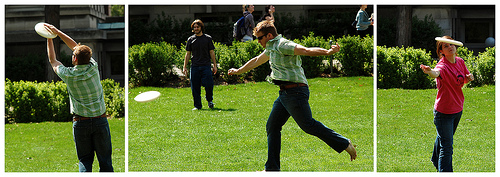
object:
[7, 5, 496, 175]
collage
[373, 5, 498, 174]
pictures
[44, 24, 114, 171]
man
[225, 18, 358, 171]
man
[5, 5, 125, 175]
left picture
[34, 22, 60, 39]
frisbee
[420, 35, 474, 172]
woman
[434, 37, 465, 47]
frisbee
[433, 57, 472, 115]
shirt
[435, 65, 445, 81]
short sleeves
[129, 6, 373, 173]
middle picture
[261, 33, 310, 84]
shirt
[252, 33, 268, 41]
sunglasses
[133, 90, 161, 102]
frisbee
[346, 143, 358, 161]
foot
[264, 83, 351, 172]
jeans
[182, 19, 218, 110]
man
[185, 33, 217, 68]
shirt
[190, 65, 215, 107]
jeans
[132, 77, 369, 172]
grass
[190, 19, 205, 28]
hair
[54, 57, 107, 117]
shirt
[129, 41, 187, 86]
bushes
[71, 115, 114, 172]
jeans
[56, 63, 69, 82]
short sleeves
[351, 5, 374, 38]
people